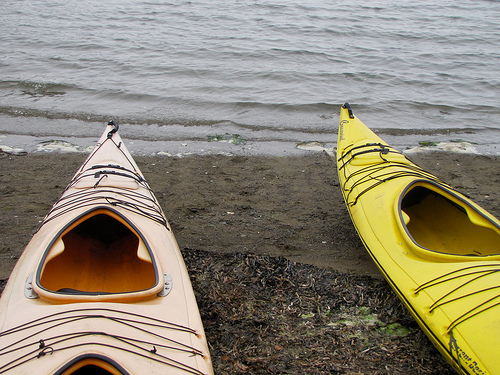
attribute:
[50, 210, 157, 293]
interior — woody-orange color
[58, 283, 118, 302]
seat — slightly visible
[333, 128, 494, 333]
kayak — yellow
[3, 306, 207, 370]
rigging — shock cord deck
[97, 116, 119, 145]
handle — grab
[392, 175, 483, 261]
opening — small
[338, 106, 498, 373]
canoe — yellow, bright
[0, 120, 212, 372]
canoe — beige, light beige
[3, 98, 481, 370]
sandy beach — dark wet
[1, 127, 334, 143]
wave — small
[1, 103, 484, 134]
wave — small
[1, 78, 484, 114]
wave — small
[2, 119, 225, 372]
kayak — peach colored, peach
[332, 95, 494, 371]
kayak — yellow, orange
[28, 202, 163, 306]
bracket — silvertone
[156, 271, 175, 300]
bolts — silvertone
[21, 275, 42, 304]
bolts — silvertone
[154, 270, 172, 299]
plate — metal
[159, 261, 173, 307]
plate — small, silver, bolted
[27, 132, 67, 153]
foam — white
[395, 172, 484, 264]
cockpit — yellow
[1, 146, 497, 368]
sand — dark brown, wet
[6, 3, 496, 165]
water — calm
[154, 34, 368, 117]
water — opaque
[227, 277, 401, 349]
leaves — dead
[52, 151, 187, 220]
ties — black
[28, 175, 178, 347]
canoe — triangle shaped